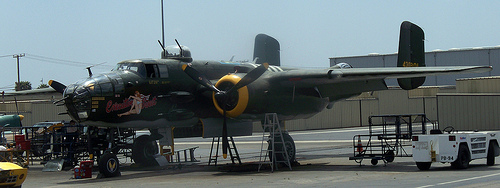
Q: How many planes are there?
A: One.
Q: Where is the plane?
A: On the ground.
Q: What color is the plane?
A: Black and yellow.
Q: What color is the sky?
A: Blue.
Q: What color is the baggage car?
A: White.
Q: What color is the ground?
A: Gray.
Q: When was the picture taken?
A: Daytime.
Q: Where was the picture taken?
A: At a military airbase.